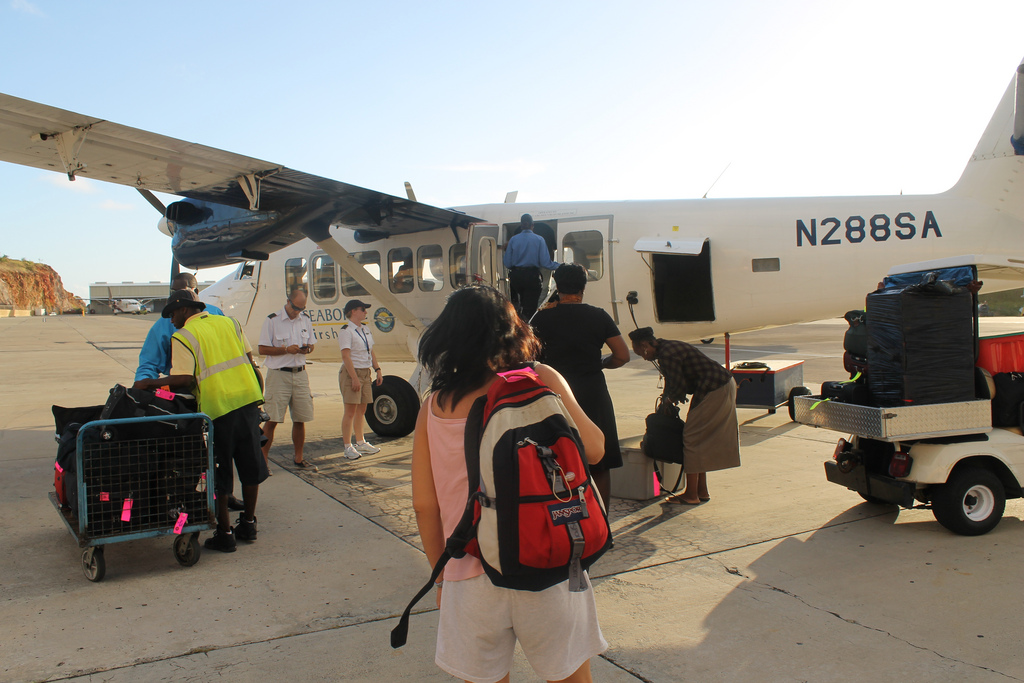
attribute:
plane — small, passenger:
[5, 74, 1021, 392]